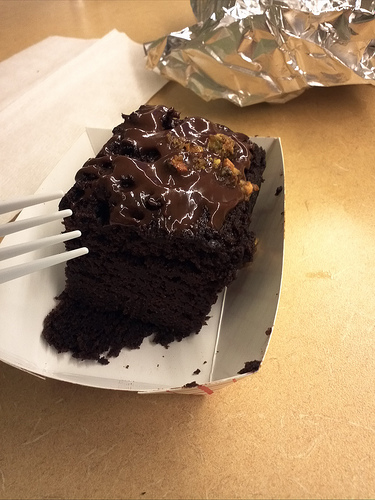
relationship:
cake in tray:
[31, 99, 276, 367] [0, 124, 288, 395]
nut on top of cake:
[222, 156, 243, 177] [31, 99, 276, 367]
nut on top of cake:
[240, 181, 254, 198] [31, 99, 276, 367]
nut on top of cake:
[166, 154, 189, 172] [31, 99, 276, 367]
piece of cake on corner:
[238, 356, 262, 372] [239, 357, 262, 374]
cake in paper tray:
[31, 99, 276, 367] [0, 124, 288, 395]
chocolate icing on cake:
[79, 102, 253, 227] [31, 99, 276, 367]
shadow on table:
[0, 361, 209, 497] [0, 1, 373, 498]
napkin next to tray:
[0, 28, 168, 223] [0, 124, 288, 395]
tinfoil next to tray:
[147, 0, 374, 110] [0, 124, 288, 395]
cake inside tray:
[31, 99, 276, 367] [0, 124, 288, 395]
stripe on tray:
[195, 384, 216, 395] [0, 124, 288, 395]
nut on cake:
[222, 156, 243, 177] [31, 99, 276, 367]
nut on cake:
[240, 181, 254, 198] [31, 99, 276, 367]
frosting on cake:
[79, 102, 253, 227] [31, 99, 276, 367]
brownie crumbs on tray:
[182, 381, 198, 389] [0, 124, 288, 395]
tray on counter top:
[0, 124, 288, 395] [0, 1, 373, 498]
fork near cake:
[0, 197, 91, 290] [31, 99, 276, 367]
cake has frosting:
[31, 99, 276, 367] [79, 102, 253, 227]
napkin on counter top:
[0, 28, 168, 223] [0, 1, 373, 498]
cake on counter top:
[31, 99, 276, 367] [0, 1, 373, 498]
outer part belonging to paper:
[147, 0, 374, 110] [141, 2, 363, 111]